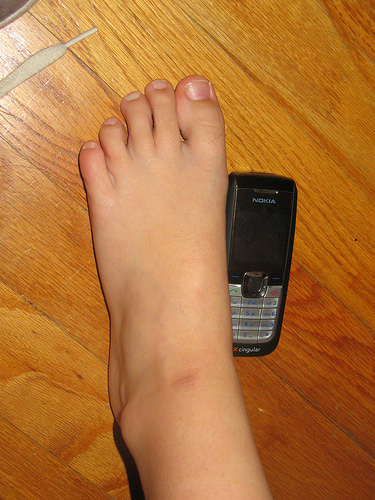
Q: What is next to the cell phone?
A: The child's little foot.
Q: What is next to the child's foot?
A: The nokia cell phone.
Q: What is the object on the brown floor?
A: Old black nokia cell phone.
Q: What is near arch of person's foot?
A: A cell phone is visible.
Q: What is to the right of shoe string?
A: A cellphone is visible.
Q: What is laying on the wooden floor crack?
A: A cell phone is visible.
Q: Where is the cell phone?
A: Next to the foot.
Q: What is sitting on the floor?
A: Cell Phone.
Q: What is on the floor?
A: A cell phone.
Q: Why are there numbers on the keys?
A: To make calls.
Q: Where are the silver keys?
A: On the cellphone.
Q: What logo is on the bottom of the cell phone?
A: Cingular.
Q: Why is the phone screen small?
A: Old school cell phone.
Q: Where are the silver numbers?
A: On the phone.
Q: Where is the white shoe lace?
A: On the floor.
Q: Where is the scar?
A: On the ankle.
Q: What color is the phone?
A: Black.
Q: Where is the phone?
A: Right side of the foot.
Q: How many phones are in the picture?
A: One.